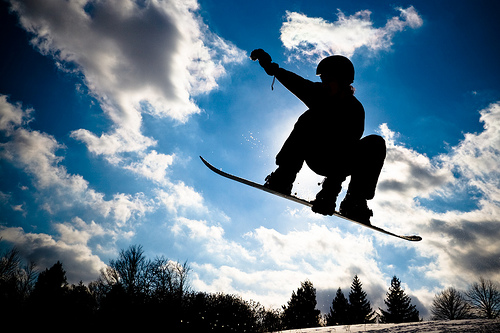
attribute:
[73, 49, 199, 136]
clouds — white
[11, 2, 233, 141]
cloud — white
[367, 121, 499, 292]
cloud — white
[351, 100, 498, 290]
clouds — white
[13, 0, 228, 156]
clouds — white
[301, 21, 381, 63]
clouds — white